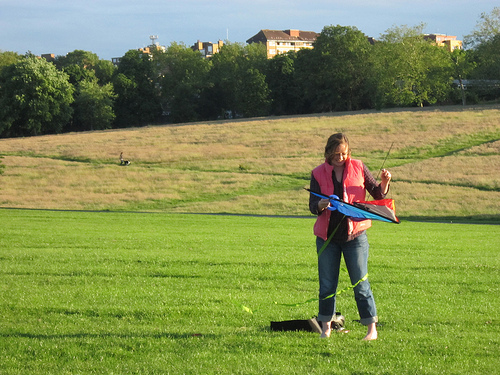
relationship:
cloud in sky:
[0, 0, 499, 61] [2, 2, 499, 61]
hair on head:
[323, 147, 370, 167] [322, 131, 352, 164]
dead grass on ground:
[36, 188, 118, 210] [0, 104, 498, 373]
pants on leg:
[305, 238, 388, 321] [305, 228, 348, 328]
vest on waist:
[313, 157, 372, 241] [303, 213, 375, 240]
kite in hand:
[344, 200, 401, 225] [378, 162, 392, 189]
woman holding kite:
[308, 132, 393, 340] [302, 183, 407, 233]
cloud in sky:
[103, 5, 353, 33] [2, 2, 499, 61]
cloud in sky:
[0, 0, 499, 61] [15, 7, 465, 55]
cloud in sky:
[0, 0, 499, 61] [0, 0, 498, 68]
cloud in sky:
[0, 0, 499, 61] [2, 2, 494, 51]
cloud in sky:
[0, 0, 499, 61] [150, 7, 282, 49]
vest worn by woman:
[311, 155, 374, 240] [308, 132, 393, 340]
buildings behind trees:
[156, 19, 472, 109] [63, 52, 247, 124]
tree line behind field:
[21, 51, 453, 117] [4, 112, 497, 373]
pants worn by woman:
[317, 233, 379, 325] [308, 132, 393, 340]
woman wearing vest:
[308, 132, 393, 340] [309, 157, 371, 242]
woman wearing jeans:
[308, 132, 393, 340] [312, 231, 380, 326]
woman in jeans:
[300, 130, 399, 370] [300, 223, 385, 315]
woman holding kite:
[300, 130, 399, 370] [298, 178, 412, 230]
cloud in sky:
[0, 0, 499, 61] [0, 0, 498, 56]